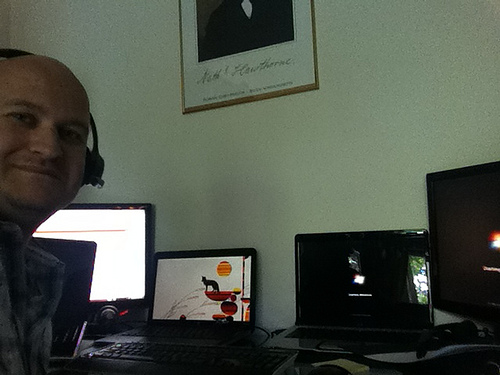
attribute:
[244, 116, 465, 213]
wal — white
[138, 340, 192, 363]
keys — black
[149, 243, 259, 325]
screen — computer, small, black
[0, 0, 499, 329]
wall — white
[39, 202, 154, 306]
computer screen — black, small, turned on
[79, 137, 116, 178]
headphones — black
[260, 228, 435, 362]
laptop — starting up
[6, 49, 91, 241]
man — bald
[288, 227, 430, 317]
screen — small, black, computer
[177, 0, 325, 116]
photo — framed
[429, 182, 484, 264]
screen — black, small, computer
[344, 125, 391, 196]
part — small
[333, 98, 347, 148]
part — small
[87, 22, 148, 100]
part — small